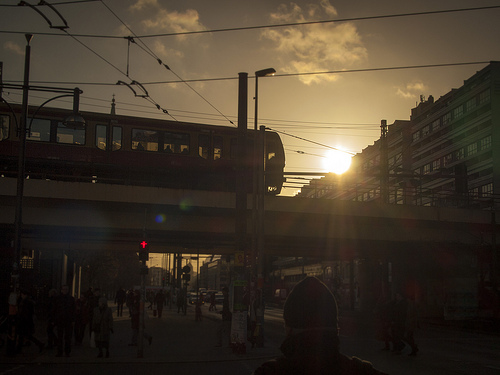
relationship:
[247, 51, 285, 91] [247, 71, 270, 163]
light and post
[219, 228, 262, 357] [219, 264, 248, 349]
pole covered in posters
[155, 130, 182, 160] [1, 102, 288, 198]
window on metro train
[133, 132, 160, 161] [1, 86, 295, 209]
window on train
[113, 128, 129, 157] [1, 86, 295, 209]
window on train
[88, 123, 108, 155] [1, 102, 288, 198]
window on metro train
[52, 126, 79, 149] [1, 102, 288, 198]
window on metro train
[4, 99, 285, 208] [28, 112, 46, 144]
window on train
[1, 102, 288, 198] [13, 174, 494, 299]
metro train on track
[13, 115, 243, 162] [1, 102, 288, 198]
windows of metro train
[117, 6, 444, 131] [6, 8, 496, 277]
clouds in sky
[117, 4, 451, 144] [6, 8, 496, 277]
clouds in sky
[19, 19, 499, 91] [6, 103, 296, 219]
railing above train